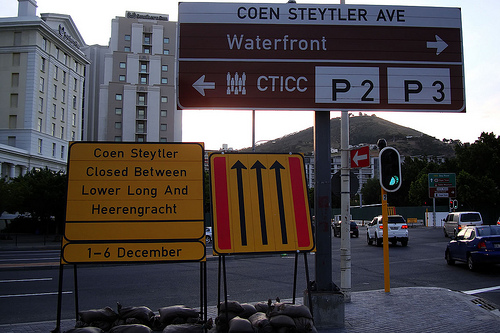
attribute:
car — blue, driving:
[445, 224, 500, 271]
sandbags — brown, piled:
[69, 296, 318, 332]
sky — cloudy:
[1, 0, 499, 150]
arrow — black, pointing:
[230, 159, 249, 247]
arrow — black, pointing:
[250, 159, 270, 245]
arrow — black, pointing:
[269, 159, 290, 246]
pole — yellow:
[381, 185, 393, 292]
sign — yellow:
[208, 150, 318, 255]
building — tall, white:
[0, 0, 182, 230]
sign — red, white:
[348, 145, 371, 167]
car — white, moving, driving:
[365, 214, 410, 246]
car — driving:
[335, 220, 359, 238]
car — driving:
[441, 209, 483, 237]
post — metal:
[217, 252, 317, 328]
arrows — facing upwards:
[228, 157, 291, 247]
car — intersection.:
[332, 215, 359, 237]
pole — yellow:
[296, 99, 375, 330]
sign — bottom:
[66, 137, 308, 256]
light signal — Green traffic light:
[373, 145, 401, 294]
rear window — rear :
[458, 213, 481, 222]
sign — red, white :
[179, 25, 464, 110]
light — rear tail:
[401, 222, 408, 234]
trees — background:
[376, 135, 498, 222]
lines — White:
[12, 285, 20, 304]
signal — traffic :
[366, 140, 403, 205]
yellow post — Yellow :
[375, 185, 397, 302]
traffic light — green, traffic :
[377, 147, 402, 194]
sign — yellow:
[57, 139, 207, 264]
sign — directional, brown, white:
[172, 2, 469, 114]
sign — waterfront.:
[179, 10, 379, 84]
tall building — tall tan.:
[2, 0, 182, 171]